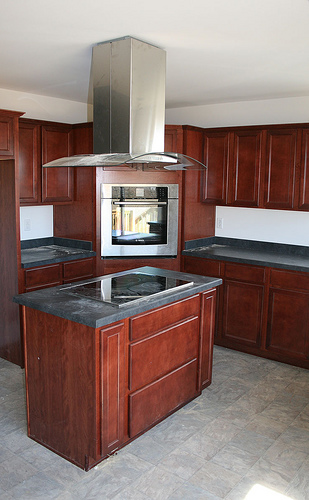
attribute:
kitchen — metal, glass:
[5, 71, 296, 401]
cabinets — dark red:
[12, 122, 298, 204]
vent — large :
[45, 36, 209, 169]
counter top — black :
[185, 238, 306, 271]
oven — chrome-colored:
[101, 180, 180, 255]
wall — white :
[3, 88, 305, 249]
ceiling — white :
[1, 0, 308, 114]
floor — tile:
[158, 446, 207, 480]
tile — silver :
[158, 445, 208, 475]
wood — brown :
[22, 309, 100, 470]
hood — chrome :
[44, 44, 202, 168]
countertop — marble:
[209, 242, 292, 267]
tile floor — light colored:
[195, 412, 276, 480]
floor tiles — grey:
[215, 409, 284, 480]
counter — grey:
[204, 239, 296, 269]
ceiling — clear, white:
[186, 44, 256, 87]